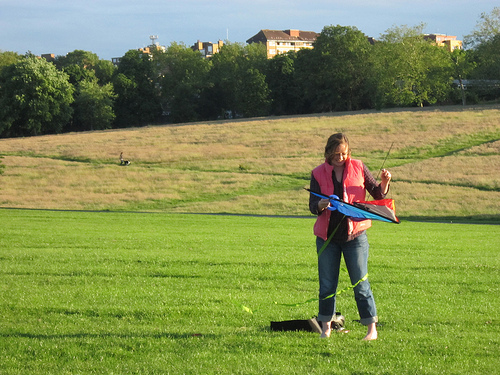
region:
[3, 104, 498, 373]
Woman is standing on a grassy field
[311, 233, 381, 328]
A pair of blue jeans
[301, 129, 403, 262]
Woman is holding a kite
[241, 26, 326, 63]
A house is in the background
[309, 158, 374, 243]
A vest is pink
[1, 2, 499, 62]
The sky appears blue and clear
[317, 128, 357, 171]
The girl has brown hair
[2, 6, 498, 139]
Green leaves on many trees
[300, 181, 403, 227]
The kite is blue, white and red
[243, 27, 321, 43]
The roof of a house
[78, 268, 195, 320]
grass on the ground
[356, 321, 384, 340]
foot on the grass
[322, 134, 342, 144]
hair on the head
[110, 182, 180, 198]
dead grass on ground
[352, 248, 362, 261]
pants on the leg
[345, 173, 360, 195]
vest on the waist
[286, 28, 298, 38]
chimney on the roof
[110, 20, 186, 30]
the sky is clear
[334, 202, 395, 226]
kite in the hand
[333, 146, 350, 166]
head of the woman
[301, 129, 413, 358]
woman holding kite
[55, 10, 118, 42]
white clouds in blue sky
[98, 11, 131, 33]
white clouds in blue sky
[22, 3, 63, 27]
white clouds in blue sky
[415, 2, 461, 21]
white clouds in blue sky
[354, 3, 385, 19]
white clouds in blue sky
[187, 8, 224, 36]
white clouds in blue sky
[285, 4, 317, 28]
white clouds in blue sky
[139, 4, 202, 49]
white clouds in blue sky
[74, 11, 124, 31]
white clouds in blue sky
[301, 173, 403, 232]
blue and red kite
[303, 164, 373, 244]
red puffy vest worn by woman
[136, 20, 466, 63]
group of buildings behind trees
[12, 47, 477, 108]
tree line behind the field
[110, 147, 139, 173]
person working in field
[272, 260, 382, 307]
neon green ribbon near woman's legs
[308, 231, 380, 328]
blue jeans worn by woman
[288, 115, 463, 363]
woman holding a kite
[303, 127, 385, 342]
woman wearing a vest and jeans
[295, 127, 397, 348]
woman in jeans holding a kite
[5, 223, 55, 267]
short green and brown grass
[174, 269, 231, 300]
short green and brown grass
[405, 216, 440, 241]
short green and brown grass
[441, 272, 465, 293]
short green and brown grass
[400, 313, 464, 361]
short green and brown grass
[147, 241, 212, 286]
short green and brown grass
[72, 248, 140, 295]
short green and brown grass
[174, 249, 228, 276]
short green and brown grass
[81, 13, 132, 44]
white clouds in blue sky